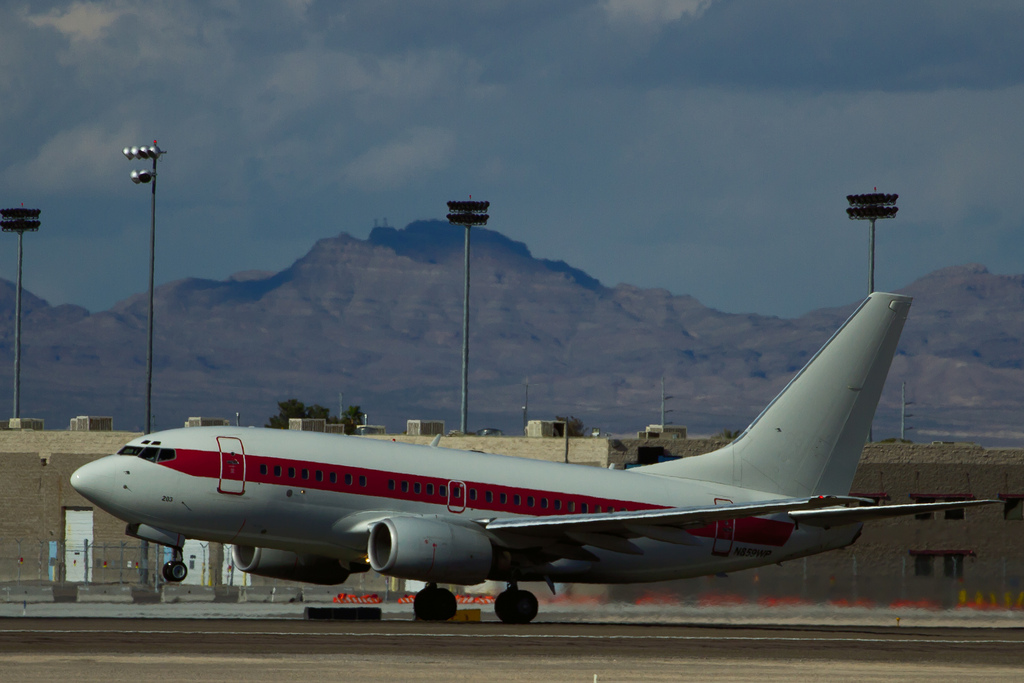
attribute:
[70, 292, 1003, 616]
stripe — red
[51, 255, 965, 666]
plane — large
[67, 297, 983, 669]
plane — large, white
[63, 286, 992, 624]
plane — large, white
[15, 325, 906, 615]
plane — large